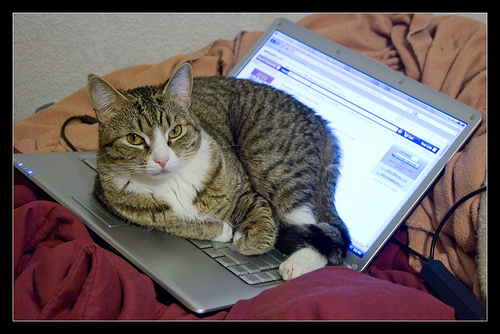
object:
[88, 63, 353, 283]
cat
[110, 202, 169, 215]
stripes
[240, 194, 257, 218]
stripes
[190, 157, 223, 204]
stripes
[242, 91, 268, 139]
stripes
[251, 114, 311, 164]
fur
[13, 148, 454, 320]
comforter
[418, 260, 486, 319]
charger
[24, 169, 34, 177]
lights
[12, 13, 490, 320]
bed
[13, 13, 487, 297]
blanket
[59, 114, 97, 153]
charging cord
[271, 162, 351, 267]
tail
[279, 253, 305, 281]
foot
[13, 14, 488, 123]
carpet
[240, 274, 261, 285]
buttons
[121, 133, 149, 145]
eyes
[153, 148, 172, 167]
nose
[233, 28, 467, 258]
screen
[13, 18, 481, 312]
laptop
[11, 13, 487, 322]
house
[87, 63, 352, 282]
image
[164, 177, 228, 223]
chest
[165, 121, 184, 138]
eye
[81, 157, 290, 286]
keyboard